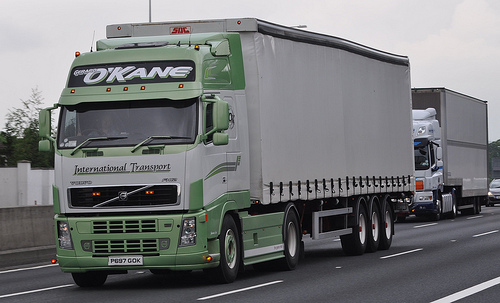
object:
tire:
[215, 203, 254, 282]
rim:
[219, 229, 249, 273]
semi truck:
[37, 18, 417, 288]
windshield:
[58, 105, 196, 142]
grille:
[91, 217, 159, 257]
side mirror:
[201, 96, 231, 146]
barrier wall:
[0, 203, 59, 255]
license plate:
[108, 253, 144, 266]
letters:
[109, 257, 114, 263]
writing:
[110, 257, 140, 264]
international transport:
[73, 161, 171, 174]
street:
[1, 207, 498, 299]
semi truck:
[412, 84, 492, 220]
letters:
[169, 66, 192, 78]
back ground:
[64, 60, 198, 86]